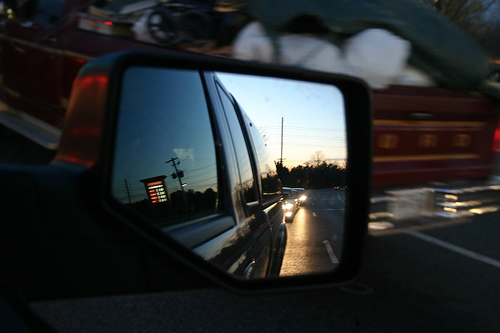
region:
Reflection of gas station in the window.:
[144, 162, 182, 218]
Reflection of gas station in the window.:
[352, 137, 449, 157]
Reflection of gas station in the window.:
[401, 66, 411, 135]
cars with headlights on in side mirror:
[279, 186, 307, 221]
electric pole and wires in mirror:
[264, 115, 347, 163]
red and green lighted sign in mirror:
[145, 173, 167, 203]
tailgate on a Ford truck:
[371, 96, 492, 186]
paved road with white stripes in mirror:
[276, 187, 344, 275]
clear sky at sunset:
[216, 73, 346, 170]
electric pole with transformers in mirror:
[166, 155, 187, 189]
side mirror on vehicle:
[2, 46, 377, 297]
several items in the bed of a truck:
[79, 0, 494, 92]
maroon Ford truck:
[0, 0, 499, 235]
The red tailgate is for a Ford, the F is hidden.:
[361, 82, 493, 181]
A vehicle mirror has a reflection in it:
[69, 45, 372, 288]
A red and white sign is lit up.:
[141, 174, 170, 208]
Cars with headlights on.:
[283, 182, 305, 219]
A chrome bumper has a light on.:
[369, 177, 497, 231]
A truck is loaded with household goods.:
[79, 4, 493, 94]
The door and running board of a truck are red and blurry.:
[3, 0, 69, 147]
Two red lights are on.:
[330, 183, 346, 193]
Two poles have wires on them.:
[119, 152, 214, 199]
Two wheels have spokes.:
[148, 7, 215, 46]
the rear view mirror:
[68, 32, 398, 309]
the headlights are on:
[265, 180, 313, 228]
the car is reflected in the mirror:
[90, 43, 318, 275]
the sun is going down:
[240, 89, 333, 153]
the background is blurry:
[385, 115, 482, 254]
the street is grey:
[303, 183, 335, 259]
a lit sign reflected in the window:
[123, 152, 190, 216]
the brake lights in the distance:
[322, 176, 345, 201]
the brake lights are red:
[322, 180, 342, 197]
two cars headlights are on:
[267, 162, 322, 234]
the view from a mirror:
[41, 24, 461, 331]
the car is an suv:
[65, 31, 433, 321]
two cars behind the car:
[93, 36, 413, 330]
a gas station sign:
[132, 160, 204, 239]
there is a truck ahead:
[70, 14, 489, 326]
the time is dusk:
[84, 40, 401, 287]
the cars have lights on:
[42, 41, 492, 296]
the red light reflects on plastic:
[41, 5, 456, 326]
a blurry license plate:
[379, 166, 451, 241]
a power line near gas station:
[138, 141, 217, 228]